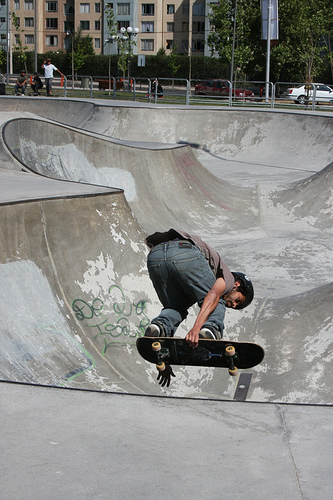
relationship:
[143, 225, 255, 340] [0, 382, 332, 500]
man going down ramp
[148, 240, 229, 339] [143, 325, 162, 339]
jeans with shoe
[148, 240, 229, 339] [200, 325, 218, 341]
jeans with shoe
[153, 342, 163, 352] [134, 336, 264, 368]
wheel on skateboard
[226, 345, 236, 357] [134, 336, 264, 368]
wheel on skateboard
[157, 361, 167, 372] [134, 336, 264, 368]
wheel on skateboard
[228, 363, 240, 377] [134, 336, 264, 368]
wheel on skateboard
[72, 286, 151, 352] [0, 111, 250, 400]
grafitti on ramp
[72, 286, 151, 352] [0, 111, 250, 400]
grafitti on side of ramp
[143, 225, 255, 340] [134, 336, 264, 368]
man holding skateboard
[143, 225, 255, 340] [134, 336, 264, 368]
man riding on skateboard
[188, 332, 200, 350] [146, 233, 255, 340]
hand of man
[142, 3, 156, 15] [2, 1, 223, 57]
window on building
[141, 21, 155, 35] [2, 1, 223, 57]
window on building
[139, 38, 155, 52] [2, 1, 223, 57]
window on building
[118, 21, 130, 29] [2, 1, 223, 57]
window on building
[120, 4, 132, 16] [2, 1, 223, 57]
window on building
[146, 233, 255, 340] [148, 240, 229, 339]
man wearing jeans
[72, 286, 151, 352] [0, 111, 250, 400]
grafitti written on ramp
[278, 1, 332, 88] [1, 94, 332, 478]
tree outside of skatepark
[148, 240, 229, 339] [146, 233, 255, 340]
jeans on man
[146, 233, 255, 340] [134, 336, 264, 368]
man holding onto skateboard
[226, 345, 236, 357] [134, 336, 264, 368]
wheel of skateboard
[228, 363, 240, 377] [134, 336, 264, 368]
wheel of skateboard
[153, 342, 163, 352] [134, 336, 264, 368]
wheel of skateboard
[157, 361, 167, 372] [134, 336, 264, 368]
wheel of skateboard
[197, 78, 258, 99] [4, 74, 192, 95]
car on road